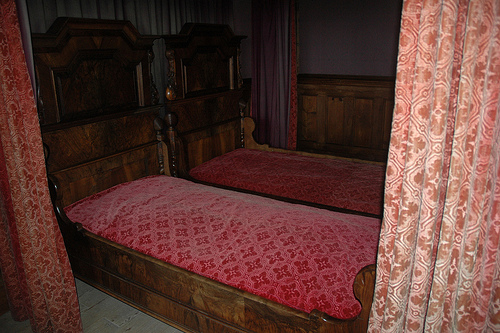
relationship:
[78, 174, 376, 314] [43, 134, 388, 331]
fabric on bed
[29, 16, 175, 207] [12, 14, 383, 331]
headboard on bed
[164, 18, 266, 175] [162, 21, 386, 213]
headboard on bed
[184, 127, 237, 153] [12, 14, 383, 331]
wood paneling on bed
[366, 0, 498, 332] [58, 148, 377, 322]
curtain next to bed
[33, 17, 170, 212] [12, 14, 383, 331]
headboard of bed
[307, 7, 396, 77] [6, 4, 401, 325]
wall in room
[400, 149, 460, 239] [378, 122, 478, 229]
design on curtain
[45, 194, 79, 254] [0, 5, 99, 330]
edge of curtain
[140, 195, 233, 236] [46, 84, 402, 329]
top of bed